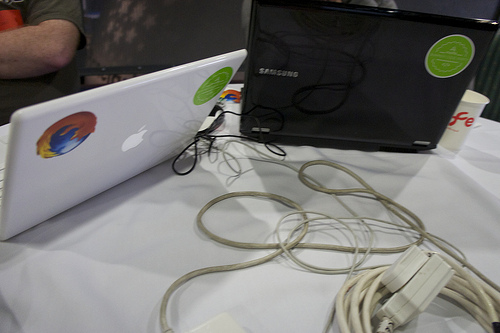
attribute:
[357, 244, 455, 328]
cord — white, coiled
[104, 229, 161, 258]
table — white, round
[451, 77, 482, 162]
coffee cup — paper, white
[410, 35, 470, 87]
sticker — green, blue, apple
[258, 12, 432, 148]
computer — white, apple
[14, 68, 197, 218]
laptop — samsung, white, black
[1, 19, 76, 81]
arm — folded, hairy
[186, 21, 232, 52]
wall — grey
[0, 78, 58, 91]
t-shirt — green